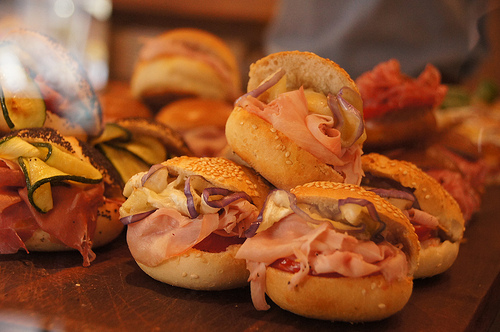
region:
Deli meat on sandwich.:
[249, 203, 401, 288]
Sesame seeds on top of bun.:
[181, 153, 251, 195]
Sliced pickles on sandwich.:
[17, 125, 94, 206]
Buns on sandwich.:
[127, 29, 244, 121]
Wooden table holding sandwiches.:
[66, 258, 165, 330]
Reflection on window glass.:
[1, 2, 113, 122]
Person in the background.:
[263, 1, 498, 100]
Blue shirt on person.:
[254, 0, 494, 87]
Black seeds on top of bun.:
[22, 120, 94, 170]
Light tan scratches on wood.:
[30, 262, 150, 323]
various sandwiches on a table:
[0, 29, 499, 327]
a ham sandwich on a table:
[238, 179, 417, 319]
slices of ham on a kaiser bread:
[242, 215, 408, 308]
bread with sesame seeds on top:
[166, 150, 271, 208]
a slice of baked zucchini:
[2, 138, 104, 210]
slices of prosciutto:
[1, 158, 102, 262]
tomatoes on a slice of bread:
[358, 62, 446, 113]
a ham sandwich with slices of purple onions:
[225, 51, 365, 188]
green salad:
[445, 83, 497, 112]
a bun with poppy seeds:
[119, 110, 196, 157]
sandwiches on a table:
[3, 6, 499, 323]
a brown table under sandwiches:
[1, 171, 498, 329]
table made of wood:
[1, 183, 497, 327]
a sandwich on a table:
[238, 174, 422, 323]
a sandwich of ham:
[235, 172, 422, 322]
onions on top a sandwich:
[283, 190, 393, 239]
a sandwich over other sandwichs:
[219, 45, 373, 193]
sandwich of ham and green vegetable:
[0, 118, 125, 259]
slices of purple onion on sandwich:
[181, 172, 251, 219]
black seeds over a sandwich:
[1, 120, 121, 182]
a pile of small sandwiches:
[110, 18, 477, 330]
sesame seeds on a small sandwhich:
[179, 148, 256, 186]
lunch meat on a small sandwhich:
[240, 207, 411, 302]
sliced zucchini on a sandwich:
[3, 40, 167, 225]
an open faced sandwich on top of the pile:
[225, 43, 376, 194]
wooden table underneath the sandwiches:
[0, 248, 498, 328]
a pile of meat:
[350, 49, 459, 131]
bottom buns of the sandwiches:
[120, 211, 417, 326]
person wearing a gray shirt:
[270, 7, 498, 90]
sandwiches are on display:
[9, 10, 451, 317]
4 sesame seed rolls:
[132, 49, 457, 310]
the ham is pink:
[247, 191, 415, 293]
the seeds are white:
[180, 149, 261, 188]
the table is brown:
[53, 245, 209, 330]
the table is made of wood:
[0, 267, 156, 317]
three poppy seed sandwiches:
[5, 46, 167, 236]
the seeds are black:
[25, 124, 108, 169]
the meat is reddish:
[1, 157, 108, 262]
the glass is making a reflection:
[12, 0, 152, 165]